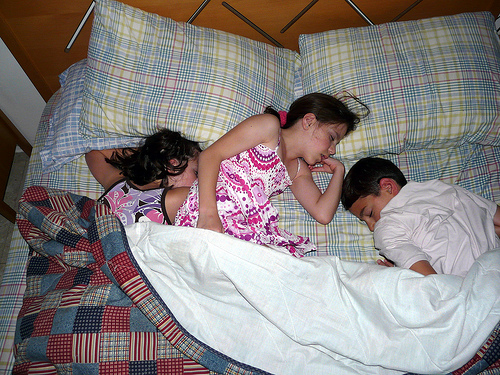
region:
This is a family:
[61, 79, 490, 269]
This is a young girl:
[212, 92, 404, 313]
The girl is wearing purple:
[87, 166, 198, 248]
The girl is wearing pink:
[190, 118, 325, 261]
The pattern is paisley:
[160, 156, 355, 297]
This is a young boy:
[331, 150, 469, 261]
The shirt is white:
[320, 230, 486, 247]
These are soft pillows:
[60, 28, 367, 158]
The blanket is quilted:
[63, 300, 150, 367]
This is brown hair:
[83, 118, 230, 203]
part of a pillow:
[165, 30, 202, 72]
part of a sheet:
[253, 236, 291, 293]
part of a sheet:
[322, 230, 334, 249]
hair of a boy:
[344, 165, 359, 215]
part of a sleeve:
[401, 242, 416, 263]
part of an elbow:
[317, 192, 334, 281]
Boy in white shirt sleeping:
[341, 158, 499, 293]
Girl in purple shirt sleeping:
[85, 140, 201, 230]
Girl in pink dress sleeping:
[173, 88, 365, 263]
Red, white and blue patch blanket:
[13, 186, 499, 373]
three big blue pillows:
[28, 3, 498, 156]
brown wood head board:
[1, 0, 498, 111]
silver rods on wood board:
[63, 0, 432, 59]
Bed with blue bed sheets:
[26, 91, 499, 368]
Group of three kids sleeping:
[69, 100, 499, 311]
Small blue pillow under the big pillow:
[47, 66, 142, 157]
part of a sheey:
[226, 258, 258, 300]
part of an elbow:
[311, 190, 326, 212]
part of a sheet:
[238, 312, 270, 367]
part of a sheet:
[233, 260, 270, 323]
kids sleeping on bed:
[107, 67, 452, 262]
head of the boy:
[325, 150, 415, 240]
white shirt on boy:
[380, 176, 481, 292]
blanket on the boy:
[336, 290, 451, 355]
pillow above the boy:
[372, 2, 477, 143]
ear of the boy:
[370, 170, 403, 210]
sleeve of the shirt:
[384, 224, 431, 276]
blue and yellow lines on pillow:
[398, 97, 479, 156]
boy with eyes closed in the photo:
[350, 165, 407, 229]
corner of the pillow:
[308, 23, 343, 66]